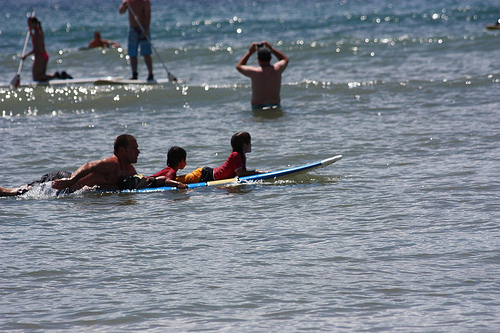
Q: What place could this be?
A: It is an ocean.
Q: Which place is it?
A: It is an ocean.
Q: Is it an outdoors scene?
A: Yes, it is outdoors.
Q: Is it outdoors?
A: Yes, it is outdoors.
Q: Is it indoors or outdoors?
A: It is outdoors.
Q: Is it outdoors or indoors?
A: It is outdoors.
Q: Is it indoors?
A: No, it is outdoors.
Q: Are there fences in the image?
A: No, there are no fences.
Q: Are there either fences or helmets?
A: No, there are no fences or helmets.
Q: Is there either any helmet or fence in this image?
A: No, there are no fences or helmets.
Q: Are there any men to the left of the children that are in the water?
A: Yes, there is a man to the left of the children.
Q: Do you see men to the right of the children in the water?
A: No, the man is to the left of the kids.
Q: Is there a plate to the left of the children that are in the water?
A: No, there is a man to the left of the kids.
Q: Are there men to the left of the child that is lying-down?
A: Yes, there is a man to the left of the kid.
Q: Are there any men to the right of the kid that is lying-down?
A: No, the man is to the left of the child.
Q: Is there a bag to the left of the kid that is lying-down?
A: No, there is a man to the left of the kid.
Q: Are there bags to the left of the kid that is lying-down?
A: No, there is a man to the left of the kid.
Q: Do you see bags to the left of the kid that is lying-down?
A: No, there is a man to the left of the kid.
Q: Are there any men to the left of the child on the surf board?
A: Yes, there is a man to the left of the kid.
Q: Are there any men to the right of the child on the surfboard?
A: No, the man is to the left of the child.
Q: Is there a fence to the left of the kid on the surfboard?
A: No, there is a man to the left of the kid.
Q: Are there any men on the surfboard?
A: Yes, there is a man on the surfboard.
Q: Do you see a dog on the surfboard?
A: No, there is a man on the surfboard.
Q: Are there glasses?
A: No, there are no glasses.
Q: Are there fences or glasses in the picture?
A: No, there are no glasses or fences.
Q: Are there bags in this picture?
A: No, there are no bags.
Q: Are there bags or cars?
A: No, there are no bags or cars.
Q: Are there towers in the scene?
A: No, there are no towers.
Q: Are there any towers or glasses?
A: No, there are no towers or glasses.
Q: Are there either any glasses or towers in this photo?
A: No, there are no towers or glasses.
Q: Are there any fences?
A: No, there are no fences.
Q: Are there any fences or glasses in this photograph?
A: No, there are no fences or glasses.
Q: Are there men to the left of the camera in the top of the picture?
A: Yes, there is a man to the left of the camera.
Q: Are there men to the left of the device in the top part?
A: Yes, there is a man to the left of the camera.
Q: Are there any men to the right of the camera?
A: No, the man is to the left of the camera.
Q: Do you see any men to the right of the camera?
A: No, the man is to the left of the camera.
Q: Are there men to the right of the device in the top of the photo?
A: No, the man is to the left of the camera.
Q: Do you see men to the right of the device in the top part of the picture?
A: No, the man is to the left of the camera.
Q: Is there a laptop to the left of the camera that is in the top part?
A: No, there is a man to the left of the camera.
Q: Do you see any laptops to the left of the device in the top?
A: No, there is a man to the left of the camera.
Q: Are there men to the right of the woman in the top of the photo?
A: Yes, there is a man to the right of the woman.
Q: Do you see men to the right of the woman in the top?
A: Yes, there is a man to the right of the woman.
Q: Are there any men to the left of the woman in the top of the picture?
A: No, the man is to the right of the woman.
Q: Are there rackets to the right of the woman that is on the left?
A: No, there is a man to the right of the woman.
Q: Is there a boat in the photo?
A: No, there are no boats.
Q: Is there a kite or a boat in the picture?
A: No, there are no boats or kites.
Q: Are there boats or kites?
A: No, there are no boats or kites.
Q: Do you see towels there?
A: No, there are no towels.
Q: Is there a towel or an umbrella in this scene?
A: No, there are no towels or umbrellas.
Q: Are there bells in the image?
A: No, there are no bells.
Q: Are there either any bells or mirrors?
A: No, there are no bells or mirrors.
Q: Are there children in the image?
A: Yes, there is a child.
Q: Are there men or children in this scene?
A: Yes, there is a child.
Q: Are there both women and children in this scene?
A: Yes, there are both a child and a woman.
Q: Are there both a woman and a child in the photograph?
A: Yes, there are both a child and a woman.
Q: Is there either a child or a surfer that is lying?
A: Yes, the child is lying.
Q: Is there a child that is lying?
A: Yes, there is a child that is lying.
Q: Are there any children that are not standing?
A: Yes, there is a child that is lying.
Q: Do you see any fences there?
A: No, there are no fences.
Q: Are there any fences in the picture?
A: No, there are no fences.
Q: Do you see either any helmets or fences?
A: No, there are no fences or helmets.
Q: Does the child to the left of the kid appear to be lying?
A: Yes, the kid is lying.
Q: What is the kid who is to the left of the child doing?
A: The child is lying.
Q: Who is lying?
A: The child is lying.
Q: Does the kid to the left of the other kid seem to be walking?
A: No, the kid is lying.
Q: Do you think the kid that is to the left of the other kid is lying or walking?
A: The kid is lying.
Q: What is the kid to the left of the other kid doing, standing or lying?
A: The kid is lying.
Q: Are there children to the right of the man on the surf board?
A: Yes, there is a child to the right of the man.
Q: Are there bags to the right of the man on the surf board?
A: No, there is a child to the right of the man.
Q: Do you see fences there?
A: No, there are no fences.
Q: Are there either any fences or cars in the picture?
A: No, there are no fences or cars.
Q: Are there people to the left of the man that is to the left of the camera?
A: Yes, there is a person to the left of the man.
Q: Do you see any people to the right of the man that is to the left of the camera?
A: No, the person is to the left of the man.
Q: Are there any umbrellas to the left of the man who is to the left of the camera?
A: No, there is a person to the left of the man.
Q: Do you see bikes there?
A: No, there are no bikes.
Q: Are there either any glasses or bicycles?
A: No, there are no bicycles or glasses.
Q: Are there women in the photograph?
A: Yes, there is a woman.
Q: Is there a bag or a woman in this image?
A: Yes, there is a woman.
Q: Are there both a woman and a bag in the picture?
A: No, there is a woman but no bags.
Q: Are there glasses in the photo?
A: No, there are no glasses.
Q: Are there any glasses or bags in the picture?
A: No, there are no glasses or bags.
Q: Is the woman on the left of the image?
A: Yes, the woman is on the left of the image.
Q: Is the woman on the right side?
A: No, the woman is on the left of the image.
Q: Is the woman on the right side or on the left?
A: The woman is on the left of the image.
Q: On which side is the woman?
A: The woman is on the left of the image.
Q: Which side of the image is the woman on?
A: The woman is on the left of the image.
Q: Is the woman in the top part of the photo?
A: Yes, the woman is in the top of the image.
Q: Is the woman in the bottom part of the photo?
A: No, the woman is in the top of the image.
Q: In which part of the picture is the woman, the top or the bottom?
A: The woman is in the top of the image.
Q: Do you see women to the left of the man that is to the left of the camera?
A: Yes, there is a woman to the left of the man.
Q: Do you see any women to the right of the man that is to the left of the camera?
A: No, the woman is to the left of the man.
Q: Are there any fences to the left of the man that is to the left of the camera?
A: No, there is a woman to the left of the man.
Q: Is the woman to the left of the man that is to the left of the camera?
A: Yes, the woman is to the left of the man.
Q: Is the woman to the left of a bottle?
A: No, the woman is to the left of the man.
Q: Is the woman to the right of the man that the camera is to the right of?
A: No, the woman is to the left of the man.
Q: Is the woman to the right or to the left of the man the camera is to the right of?
A: The woman is to the left of the man.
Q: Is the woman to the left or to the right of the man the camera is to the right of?
A: The woman is to the left of the man.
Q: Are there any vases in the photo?
A: No, there are no vases.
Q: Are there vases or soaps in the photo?
A: No, there are no vases or soaps.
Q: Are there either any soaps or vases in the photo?
A: No, there are no vases or soaps.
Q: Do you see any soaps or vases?
A: No, there are no vases or soaps.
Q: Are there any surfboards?
A: Yes, there is a surfboard.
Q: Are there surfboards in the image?
A: Yes, there is a surfboard.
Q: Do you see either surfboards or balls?
A: Yes, there is a surfboard.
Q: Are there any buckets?
A: No, there are no buckets.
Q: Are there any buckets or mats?
A: No, there are no buckets or mats.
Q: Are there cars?
A: No, there are no cars.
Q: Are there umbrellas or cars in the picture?
A: No, there are no cars or umbrellas.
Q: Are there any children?
A: Yes, there is a child.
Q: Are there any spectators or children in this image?
A: Yes, there is a child.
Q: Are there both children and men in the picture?
A: Yes, there are both a child and a man.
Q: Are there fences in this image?
A: No, there are no fences.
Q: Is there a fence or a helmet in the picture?
A: No, there are no fences or helmets.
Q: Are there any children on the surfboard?
A: Yes, there is a child on the surfboard.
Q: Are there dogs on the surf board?
A: No, there is a child on the surf board.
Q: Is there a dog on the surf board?
A: No, there is a child on the surf board.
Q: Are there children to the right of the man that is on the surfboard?
A: Yes, there is a child to the right of the man.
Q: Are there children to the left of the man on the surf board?
A: No, the child is to the right of the man.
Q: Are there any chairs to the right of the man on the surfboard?
A: No, there is a child to the right of the man.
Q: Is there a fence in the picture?
A: No, there are no fences.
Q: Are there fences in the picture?
A: No, there are no fences.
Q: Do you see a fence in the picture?
A: No, there are no fences.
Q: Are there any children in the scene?
A: Yes, there are children.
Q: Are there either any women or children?
A: Yes, there are children.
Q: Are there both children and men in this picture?
A: Yes, there are both children and a man.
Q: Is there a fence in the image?
A: No, there are no fences.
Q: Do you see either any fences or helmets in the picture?
A: No, there are no fences or helmets.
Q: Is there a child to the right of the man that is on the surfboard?
A: Yes, there are children to the right of the man.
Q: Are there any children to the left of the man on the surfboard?
A: No, the children are to the right of the man.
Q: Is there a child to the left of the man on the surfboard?
A: No, the children are to the right of the man.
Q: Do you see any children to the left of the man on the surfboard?
A: No, the children are to the right of the man.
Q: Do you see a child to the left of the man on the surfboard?
A: No, the children are to the right of the man.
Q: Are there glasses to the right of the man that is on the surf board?
A: No, there are children to the right of the man.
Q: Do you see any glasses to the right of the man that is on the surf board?
A: No, there are children to the right of the man.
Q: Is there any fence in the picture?
A: No, there are no fences.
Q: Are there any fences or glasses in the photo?
A: No, there are no fences or glasses.